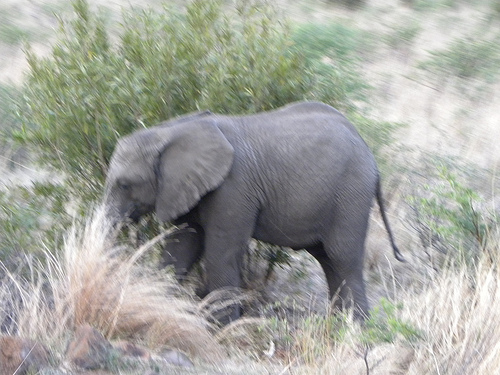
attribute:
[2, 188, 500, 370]
ground — yellow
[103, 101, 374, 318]
elephant — standing, small, massive, grey, baby, walking, wide, fat, short, thick, big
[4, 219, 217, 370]
bush — yellow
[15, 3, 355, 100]
bush — large, green, big, wide, light green, messy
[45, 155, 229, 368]
grass — high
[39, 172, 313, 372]
grass — dry, long